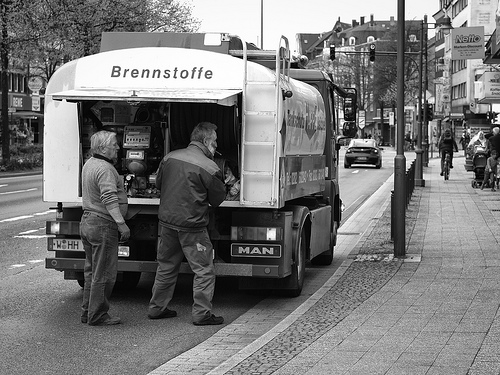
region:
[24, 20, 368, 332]
two men standing at the back of a truck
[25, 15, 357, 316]
the truck says brennstoffe on the back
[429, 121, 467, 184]
a person is riding a bicycle on the sidewalk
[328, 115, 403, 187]
a car is on the road in front of the truck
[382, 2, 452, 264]
light poles line the sidewalk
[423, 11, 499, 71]
a sign that says netto hangs from the building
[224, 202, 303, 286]
the back of the truck says man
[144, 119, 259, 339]
the man on the right is wearing a jacket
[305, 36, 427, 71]
the traffic lights are lit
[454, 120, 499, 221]
people are on the sidewalk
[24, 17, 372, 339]
two men behind truck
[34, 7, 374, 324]
truck with good in it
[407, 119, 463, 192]
man on a bicycle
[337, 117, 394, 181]
car driving on the road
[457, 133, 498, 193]
stroller on side of the road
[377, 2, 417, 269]
lamp post on side walk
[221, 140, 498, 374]
brick paved side walk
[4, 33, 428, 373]
tar covered road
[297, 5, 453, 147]
buildings in the distance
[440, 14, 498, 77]
sign on building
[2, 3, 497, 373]
the photo is in black and white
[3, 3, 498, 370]
the photo was taken outdoors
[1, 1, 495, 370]
it is a daytime scene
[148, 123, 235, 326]
the man is wearing a two tone jacket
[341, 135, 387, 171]
there is the back of a car seen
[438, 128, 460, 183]
a man is riding a bicycle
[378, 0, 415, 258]
a street pole on the sidewalk can be seen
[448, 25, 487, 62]
a sign is hanging over the sidewalk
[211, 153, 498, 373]
the sidewalk is brick layered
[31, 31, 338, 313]
the truck is facing back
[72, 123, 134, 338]
Old man with sleeve shirt pushed up.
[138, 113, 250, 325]
Old man wearing a jacket.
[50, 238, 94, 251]
License plate on the back of the truck.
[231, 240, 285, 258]
Label with the letters MAN on the back of the truck.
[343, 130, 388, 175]
Car in front of the truck.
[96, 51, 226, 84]
Name on the top of the truck beginning with the letter B.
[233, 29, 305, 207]
Ladder on truck leading to the top of the truck.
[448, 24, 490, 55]
White business sign beginning with the letter N.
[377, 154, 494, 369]
Sidewalk where people are on the right side.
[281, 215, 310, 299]
Back wheel of the truck.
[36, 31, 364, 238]
Truck on the street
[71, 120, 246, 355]
Men behind a truck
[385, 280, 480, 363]
bricks on a sidewalk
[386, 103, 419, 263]
Street light pole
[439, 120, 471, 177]
Person riding a bike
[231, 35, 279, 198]
Ladder on a truck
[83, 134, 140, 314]
Man standing behind a truck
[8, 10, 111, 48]
Trees by the street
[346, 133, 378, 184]
Car driving on the road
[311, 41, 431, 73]
Stop lights by a street